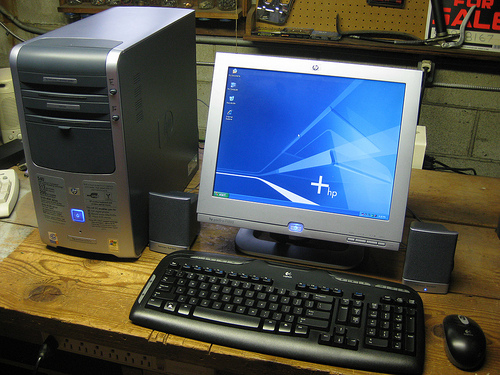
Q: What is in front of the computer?
A: A keyboard.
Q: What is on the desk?
A: A computer monitor.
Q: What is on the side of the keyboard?
A: A computer mouse.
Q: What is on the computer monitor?
A: A blue screen.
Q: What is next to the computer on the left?
A: A silver CPU.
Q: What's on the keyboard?
A: Black keys.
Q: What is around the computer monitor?
A: A grey frame.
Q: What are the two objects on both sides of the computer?
A: Speakers.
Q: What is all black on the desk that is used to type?
A: The keyboard.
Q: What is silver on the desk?
A: The monitor.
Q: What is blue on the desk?
A: The monitor background.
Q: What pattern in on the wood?
A: Circles and curves.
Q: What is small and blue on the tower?
A: The on/off button.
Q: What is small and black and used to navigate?
A: The mouse.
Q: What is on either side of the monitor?
A: Speakers.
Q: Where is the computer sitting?
A: On the desk.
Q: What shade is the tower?
A: Black and silver.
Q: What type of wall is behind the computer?
A: Pegboard.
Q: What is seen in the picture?
A: Computer.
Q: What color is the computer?
A: Black.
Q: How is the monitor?
A: On.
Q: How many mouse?
A: One.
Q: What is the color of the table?
A: Brown.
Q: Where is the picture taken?
A: In a workshop.